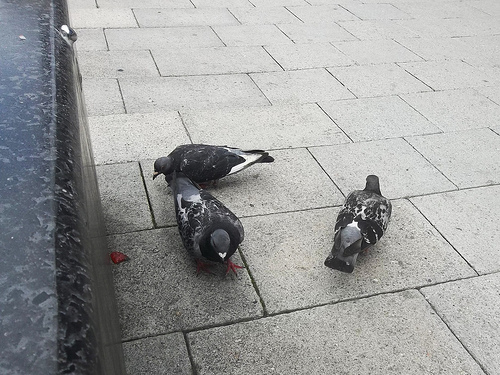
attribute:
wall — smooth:
[6, 0, 133, 373]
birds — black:
[134, 125, 409, 284]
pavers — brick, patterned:
[72, 21, 272, 98]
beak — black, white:
[151, 172, 162, 180]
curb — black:
[0, 0, 129, 373]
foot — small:
[222, 259, 248, 279]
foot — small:
[190, 259, 216, 278]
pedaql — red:
[109, 248, 131, 266]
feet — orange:
[223, 258, 248, 278]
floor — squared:
[79, 18, 496, 174]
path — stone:
[148, 281, 223, 344]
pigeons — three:
[240, 185, 391, 258]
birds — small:
[105, 67, 474, 307]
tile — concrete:
[220, 176, 473, 333]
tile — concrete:
[189, 275, 484, 373]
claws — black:
[183, 257, 248, 281]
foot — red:
[226, 258, 248, 281]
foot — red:
[193, 259, 220, 279]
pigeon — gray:
[171, 171, 245, 278]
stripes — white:
[358, 205, 368, 224]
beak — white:
[200, 247, 238, 269]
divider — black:
[0, 0, 127, 372]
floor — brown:
[89, 35, 484, 362]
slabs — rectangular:
[88, 37, 468, 308]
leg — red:
[225, 252, 247, 270]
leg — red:
[191, 247, 218, 272]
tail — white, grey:
[218, 131, 303, 200]